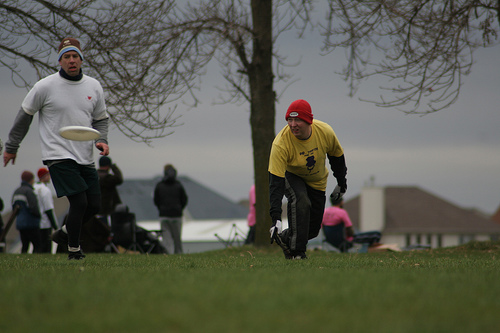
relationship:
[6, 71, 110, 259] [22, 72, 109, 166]
man wearing shirt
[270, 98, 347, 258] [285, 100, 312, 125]
man wearing cap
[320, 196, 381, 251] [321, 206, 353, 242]
person wearing pink shirt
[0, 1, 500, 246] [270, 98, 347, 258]
tree behind man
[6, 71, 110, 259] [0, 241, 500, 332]
man running on field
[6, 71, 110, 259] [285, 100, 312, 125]
man wearing cap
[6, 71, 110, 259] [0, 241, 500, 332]
man standing on field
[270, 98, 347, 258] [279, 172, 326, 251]
man wearing pants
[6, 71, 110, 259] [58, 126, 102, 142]
man playing frisbee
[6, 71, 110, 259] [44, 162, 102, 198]
man wearing shorts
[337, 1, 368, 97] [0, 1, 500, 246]
branch of tree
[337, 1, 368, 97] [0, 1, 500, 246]
branch on tree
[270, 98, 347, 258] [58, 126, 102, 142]
man watching frisbee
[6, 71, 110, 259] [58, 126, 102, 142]
man watches frisbee